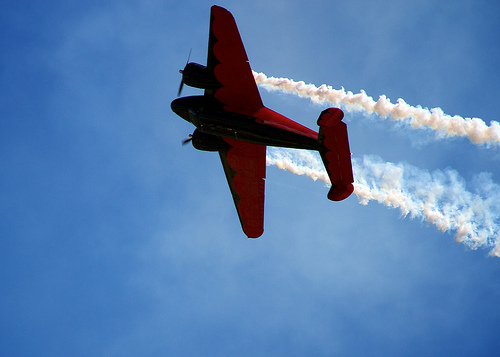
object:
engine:
[181, 126, 233, 156]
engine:
[176, 57, 215, 97]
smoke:
[260, 146, 500, 260]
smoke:
[250, 74, 500, 148]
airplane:
[169, 5, 358, 242]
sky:
[0, 0, 500, 357]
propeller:
[174, 46, 194, 98]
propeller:
[182, 130, 200, 146]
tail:
[315, 106, 356, 203]